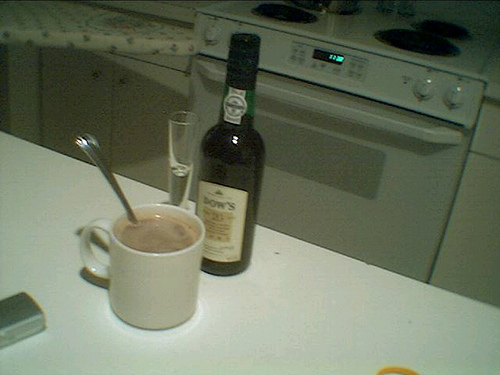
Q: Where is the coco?
A: Top of counter.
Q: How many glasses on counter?
A: One.